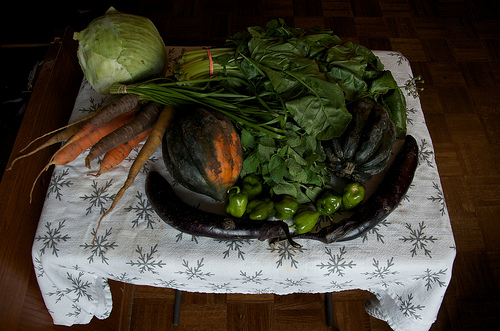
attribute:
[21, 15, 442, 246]
tablecloth — white, plenty, green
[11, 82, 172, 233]
carrots — dirty, orange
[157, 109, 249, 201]
squash — acorn, green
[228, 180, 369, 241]
peppers — green, small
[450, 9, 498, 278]
floor — brown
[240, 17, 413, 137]
greens — numerous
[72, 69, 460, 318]
tablecloth — white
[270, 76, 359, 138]
leaf — green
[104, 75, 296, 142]
onions — green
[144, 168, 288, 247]
pepper — long